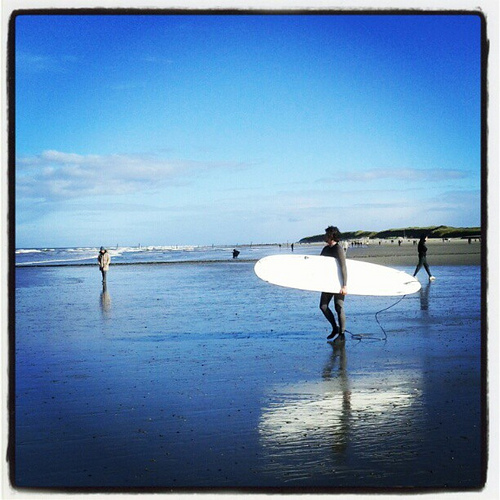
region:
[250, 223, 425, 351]
Surfer carrying a surfboard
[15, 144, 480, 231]
Clouds in the sky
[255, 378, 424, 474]
A surfer and surfboard's reflection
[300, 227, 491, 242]
Mountains in the distance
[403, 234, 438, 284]
A person walking on the beach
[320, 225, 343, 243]
The surfer has dark hair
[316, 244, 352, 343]
Surfer is wearing a wetsuit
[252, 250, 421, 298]
Surfboard in the surfer's hands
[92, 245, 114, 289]
Person wearing a white jacket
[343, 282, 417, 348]
A rope hanging from the surfboard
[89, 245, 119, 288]
woman standing in wet area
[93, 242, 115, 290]
woman wearing a blue beanie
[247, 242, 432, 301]
long white surf board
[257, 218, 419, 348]
man carrying a surfboard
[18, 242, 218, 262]
ocean waves in background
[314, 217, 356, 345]
man wearing a dark wetsuit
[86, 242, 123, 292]
woman looking down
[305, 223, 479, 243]
mountain range in background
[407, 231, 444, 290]
person in wet suit walking away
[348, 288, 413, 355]
string attached to surf board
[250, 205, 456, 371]
people walking on the beach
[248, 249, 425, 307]
white surfboard under arm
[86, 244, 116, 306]
person standing in the water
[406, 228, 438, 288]
person walking in the water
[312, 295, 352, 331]
legs in a wetsuit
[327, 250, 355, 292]
arm in wet suit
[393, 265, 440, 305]
end of surf board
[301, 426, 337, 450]
reflection from the board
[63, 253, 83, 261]
white ocean water waves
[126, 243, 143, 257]
frothy ocean water waves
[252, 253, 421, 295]
A long white surf board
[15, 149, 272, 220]
White cloud in the sky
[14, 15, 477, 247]
A blue sky above.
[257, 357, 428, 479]
A reflection on the ground.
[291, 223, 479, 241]
Green hills in the background.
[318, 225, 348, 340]
A surfer wearing a wet suit.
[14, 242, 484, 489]
A beach scene.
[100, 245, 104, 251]
A light blue hat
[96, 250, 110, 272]
A grey coat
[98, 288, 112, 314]
reflection of a man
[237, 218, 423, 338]
surfer walking into the ocean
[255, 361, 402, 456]
reflection of surfer carrying white surfboard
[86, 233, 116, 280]
person walking through shallow water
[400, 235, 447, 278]
person walking away from ocean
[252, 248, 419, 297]
white surfboard being carried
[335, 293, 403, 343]
black cord and ankle strap of surfboard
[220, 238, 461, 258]
people along the shoreline int he distance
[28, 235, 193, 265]
waves crashing in the ocean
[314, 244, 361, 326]
wetsuit of man with surfboard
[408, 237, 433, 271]
outfit of person walking out of ocean